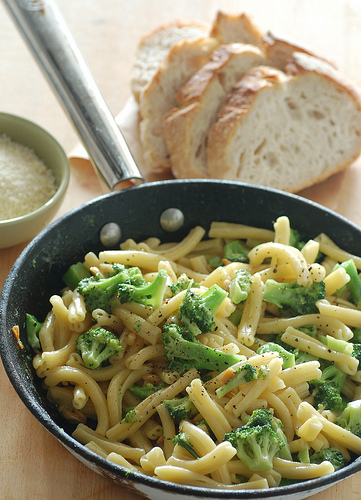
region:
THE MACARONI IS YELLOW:
[28, 212, 360, 491]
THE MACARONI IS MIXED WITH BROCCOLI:
[17, 212, 359, 492]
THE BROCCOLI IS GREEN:
[20, 227, 359, 470]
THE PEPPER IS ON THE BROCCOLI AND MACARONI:
[13, 214, 360, 491]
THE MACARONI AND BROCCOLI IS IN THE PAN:
[1, 0, 360, 498]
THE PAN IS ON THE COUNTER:
[0, 128, 358, 498]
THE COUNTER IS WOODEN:
[2, 150, 359, 498]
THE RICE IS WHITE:
[0, 132, 59, 226]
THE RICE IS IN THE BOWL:
[0, 110, 73, 250]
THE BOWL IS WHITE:
[0, 109, 73, 250]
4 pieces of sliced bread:
[112, 9, 358, 187]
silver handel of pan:
[6, 1, 145, 190]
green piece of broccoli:
[157, 313, 245, 376]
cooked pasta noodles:
[50, 358, 138, 436]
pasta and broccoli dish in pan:
[2, 182, 359, 498]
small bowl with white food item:
[1, 81, 74, 251]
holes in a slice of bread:
[255, 85, 347, 166]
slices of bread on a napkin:
[43, 12, 350, 182]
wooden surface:
[4, 436, 49, 497]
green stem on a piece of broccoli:
[141, 266, 173, 310]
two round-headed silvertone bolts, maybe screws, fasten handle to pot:
[91, 198, 191, 251]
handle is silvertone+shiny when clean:
[0, 0, 154, 201]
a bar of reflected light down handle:
[48, 0, 164, 185]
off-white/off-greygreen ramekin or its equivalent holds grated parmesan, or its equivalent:
[0, 106, 76, 250]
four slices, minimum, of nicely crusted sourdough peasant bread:
[112, 2, 360, 192]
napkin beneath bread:
[38, 91, 171, 199]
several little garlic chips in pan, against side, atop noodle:
[10, 252, 242, 444]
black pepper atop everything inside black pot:
[14, 235, 339, 461]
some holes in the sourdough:
[222, 88, 358, 194]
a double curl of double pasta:
[39, 359, 117, 443]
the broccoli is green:
[23, 223, 360, 477]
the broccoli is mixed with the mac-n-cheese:
[25, 222, 360, 470]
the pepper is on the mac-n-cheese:
[14, 212, 360, 491]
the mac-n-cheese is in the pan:
[11, 214, 359, 491]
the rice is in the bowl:
[0, 108, 73, 250]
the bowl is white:
[0, 108, 72, 251]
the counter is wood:
[0, 115, 359, 498]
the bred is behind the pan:
[120, 8, 359, 191]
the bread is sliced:
[116, 7, 359, 197]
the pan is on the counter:
[0, 0, 359, 499]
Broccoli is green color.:
[69, 264, 349, 444]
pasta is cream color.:
[65, 261, 329, 450]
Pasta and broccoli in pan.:
[17, 181, 342, 494]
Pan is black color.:
[3, 356, 86, 467]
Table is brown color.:
[10, 427, 88, 493]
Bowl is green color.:
[15, 127, 83, 215]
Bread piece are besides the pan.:
[141, 28, 295, 136]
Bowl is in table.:
[11, 89, 76, 180]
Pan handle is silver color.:
[17, 14, 142, 197]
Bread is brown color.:
[144, 43, 293, 149]